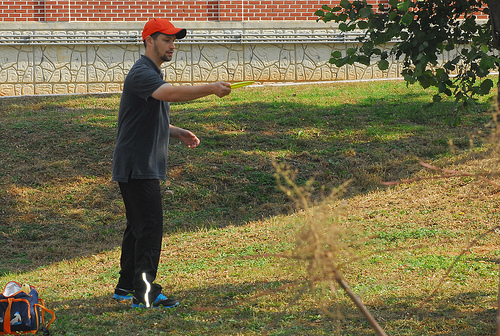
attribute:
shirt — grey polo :
[111, 54, 170, 181]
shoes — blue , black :
[114, 280, 186, 310]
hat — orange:
[135, 6, 191, 46]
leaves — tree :
[373, 7, 497, 84]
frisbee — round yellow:
[225, 78, 260, 91]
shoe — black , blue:
[131, 290, 179, 307]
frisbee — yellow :
[228, 77, 258, 87]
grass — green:
[2, 67, 499, 334]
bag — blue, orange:
[3, 274, 63, 333]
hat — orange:
[106, 0, 203, 54]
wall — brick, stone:
[16, 8, 101, 67]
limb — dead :
[249, 200, 417, 308]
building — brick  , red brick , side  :
[0, 3, 498, 103]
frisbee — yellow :
[228, 78, 254, 89]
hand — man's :
[213, 78, 230, 99]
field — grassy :
[199, 84, 485, 321]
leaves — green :
[309, 2, 499, 125]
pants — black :
[108, 173, 178, 290]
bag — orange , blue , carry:
[2, 277, 64, 331]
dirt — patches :
[213, 263, 278, 288]